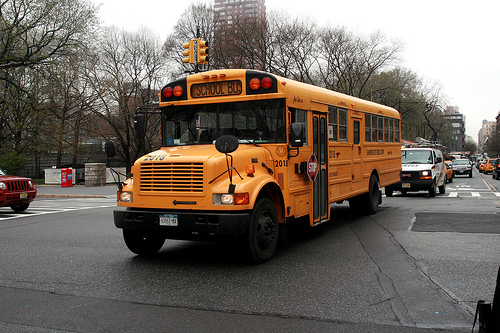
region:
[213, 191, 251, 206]
HEAD LIGHT FOR SCHOOL BUS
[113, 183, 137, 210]
HEADLIGHT FOR SCHOOL BUS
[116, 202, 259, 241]
FRONT BUMPER FOR BUS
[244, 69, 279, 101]
CAUTION LIGHT FOR BUS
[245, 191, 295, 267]
FRONT TIRE OF BUS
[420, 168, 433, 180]
HEADLIGHT OF SMALL CAR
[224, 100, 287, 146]
WINDSHIELD OF SCHOOL BUS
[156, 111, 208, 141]
WINDSHIELD OF SCHOOL BUS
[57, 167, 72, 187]
a red newspaper stand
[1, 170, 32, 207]
a red car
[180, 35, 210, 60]
a street light above the bus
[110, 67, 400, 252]
a yellow school bus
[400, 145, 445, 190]
a white van behind the bus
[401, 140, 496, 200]
cars on the street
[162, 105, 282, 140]
the wind shield on the bus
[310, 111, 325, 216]
the door on the bus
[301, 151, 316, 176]
the stop sign on the bus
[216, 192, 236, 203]
the headlight on the bus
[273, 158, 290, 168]
a number on the bus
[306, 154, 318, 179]
a stop sign on the side of the bus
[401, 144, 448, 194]
a white van behind the bus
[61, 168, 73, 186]
a red newspaper stand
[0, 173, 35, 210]
the front end of a SUV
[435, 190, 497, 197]
pedestrian crossing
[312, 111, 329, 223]
a passenger door is closed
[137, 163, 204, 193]
the grill is painted yellow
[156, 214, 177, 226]
the license plate is white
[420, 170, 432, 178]
the headlight is on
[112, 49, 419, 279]
yellow school bus on road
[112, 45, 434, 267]
yellow school bus on road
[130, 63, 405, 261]
yellow school bus on road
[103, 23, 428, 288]
yellow school bus on road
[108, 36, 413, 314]
yellow school bus on road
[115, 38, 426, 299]
yellow school bus on road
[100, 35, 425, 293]
yellow school bus on road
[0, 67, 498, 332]
Many cars are traveling on road.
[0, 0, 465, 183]
Trees with no leaves line the road.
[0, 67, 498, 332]
School bus is driving through intersection.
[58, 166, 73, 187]
Newspaper stand is red.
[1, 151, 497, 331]
Concrete on street is wet.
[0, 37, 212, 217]
Red vehicle is waiting at stop light.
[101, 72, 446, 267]
White van is following school bus.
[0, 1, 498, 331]
Busy street with many cars.